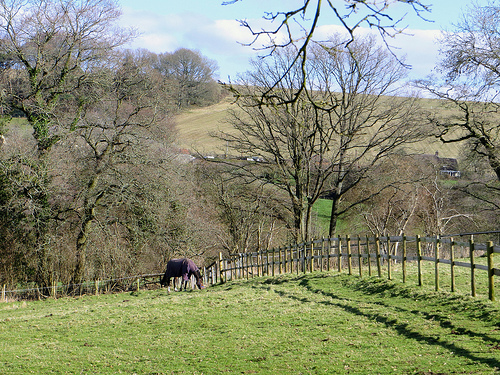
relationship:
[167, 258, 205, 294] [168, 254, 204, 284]
blanket in a blanket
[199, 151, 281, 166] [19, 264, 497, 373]
buildings over grass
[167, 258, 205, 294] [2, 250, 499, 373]
blanket in field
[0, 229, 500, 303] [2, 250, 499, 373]
fence in field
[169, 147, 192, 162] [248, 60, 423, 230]
buildings behind trees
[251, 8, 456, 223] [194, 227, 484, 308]
trees behind fence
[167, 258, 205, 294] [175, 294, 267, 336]
blanket eating grass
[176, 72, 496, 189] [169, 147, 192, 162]
field behind buildings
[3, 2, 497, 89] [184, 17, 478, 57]
sky with clouds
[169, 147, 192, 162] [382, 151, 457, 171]
buildings with roof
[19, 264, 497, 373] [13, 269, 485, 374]
grass in pasture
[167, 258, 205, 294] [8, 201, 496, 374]
blanket in field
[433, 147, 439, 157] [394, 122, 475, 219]
chimney of house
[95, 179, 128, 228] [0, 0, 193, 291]
branches from trees